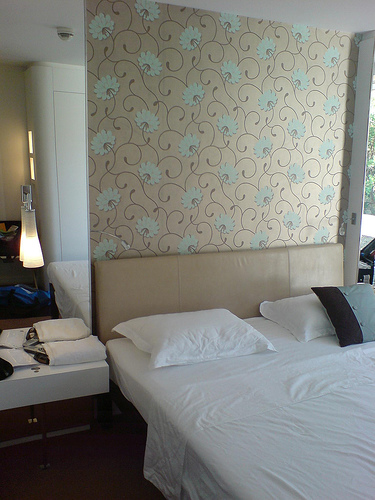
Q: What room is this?
A: Bedroom.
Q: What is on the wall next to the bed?
A: Mirror.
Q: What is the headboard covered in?
A: Leather.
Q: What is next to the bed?
A: Night stand.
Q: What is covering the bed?
A: Sheet.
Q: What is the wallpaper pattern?
A: Floral.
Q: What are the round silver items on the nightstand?
A: Coins.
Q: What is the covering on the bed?
A: Sheets.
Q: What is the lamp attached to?
A: Mirror.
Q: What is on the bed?
A: White pillows.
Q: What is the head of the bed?
A: Dark grey.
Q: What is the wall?
A: Grey and blue.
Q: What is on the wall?
A: Blue flowers.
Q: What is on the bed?
A: White bed sheets and white pillows.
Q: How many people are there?
A: None.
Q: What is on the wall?
A: Flowers.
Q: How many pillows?
A: Three.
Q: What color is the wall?
A: Brown.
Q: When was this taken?
A: During the day.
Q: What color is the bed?
A: White.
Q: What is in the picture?
A: A bedroom.